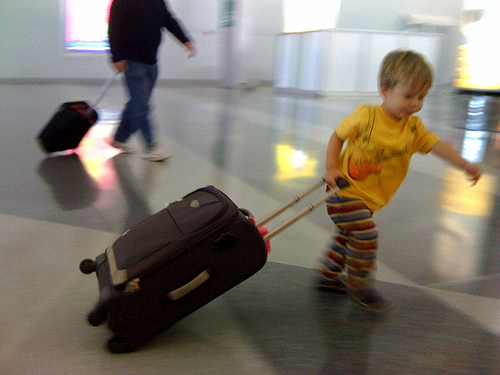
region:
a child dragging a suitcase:
[78, 46, 481, 352]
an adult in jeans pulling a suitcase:
[30, 0, 195, 161]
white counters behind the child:
[270, 25, 445, 90]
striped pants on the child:
[315, 185, 375, 285]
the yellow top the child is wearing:
[335, 105, 435, 205]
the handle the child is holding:
[315, 165, 345, 190]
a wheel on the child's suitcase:
[70, 255, 90, 270]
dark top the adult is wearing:
[105, 0, 185, 60]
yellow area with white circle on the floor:
[275, 145, 310, 175]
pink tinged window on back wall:
[61, 0, 111, 51]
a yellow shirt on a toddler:
[327, 106, 440, 210]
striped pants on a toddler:
[315, 184, 379, 288]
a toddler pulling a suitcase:
[310, 49, 481, 314]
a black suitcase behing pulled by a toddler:
[79, 184, 269, 350]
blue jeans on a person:
[114, 59, 163, 150]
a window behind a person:
[60, 1, 113, 54]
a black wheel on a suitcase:
[80, 257, 94, 274]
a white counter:
[269, 29, 443, 94]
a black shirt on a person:
[105, 0, 190, 62]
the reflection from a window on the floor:
[69, 114, 135, 186]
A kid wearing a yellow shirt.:
[333, 119, 430, 224]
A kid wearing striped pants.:
[328, 183, 388, 298]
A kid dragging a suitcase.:
[76, 120, 466, 345]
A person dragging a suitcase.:
[12, 20, 189, 182]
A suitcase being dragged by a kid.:
[91, 201, 430, 312]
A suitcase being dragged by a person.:
[27, 7, 186, 173]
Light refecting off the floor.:
[245, 103, 319, 185]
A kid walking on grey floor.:
[337, 48, 477, 374]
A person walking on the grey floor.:
[78, 5, 188, 161]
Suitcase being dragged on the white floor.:
[69, 182, 305, 344]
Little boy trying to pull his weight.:
[66, 43, 483, 342]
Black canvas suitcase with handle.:
[66, 174, 357, 359]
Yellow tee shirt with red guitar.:
[313, 100, 468, 216]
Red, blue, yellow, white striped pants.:
[313, 174, 389, 319]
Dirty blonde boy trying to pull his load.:
[305, 38, 489, 320]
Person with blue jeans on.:
[108, 0, 198, 175]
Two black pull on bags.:
[32, 60, 346, 355]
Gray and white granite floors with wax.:
[63, 110, 490, 369]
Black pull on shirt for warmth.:
[95, 2, 212, 74]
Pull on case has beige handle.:
[71, 169, 370, 359]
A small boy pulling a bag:
[312, 47, 481, 312]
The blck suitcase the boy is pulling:
[80, 185, 267, 353]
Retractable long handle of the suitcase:
[255, 175, 351, 240]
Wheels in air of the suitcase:
[80, 256, 105, 326]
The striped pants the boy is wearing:
[310, 186, 375, 286]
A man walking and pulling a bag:
[106, 0, 192, 160]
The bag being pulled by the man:
[37, 100, 97, 152]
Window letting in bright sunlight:
[60, 0, 106, 46]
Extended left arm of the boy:
[415, 116, 481, 186]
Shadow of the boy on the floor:
[312, 288, 382, 372]